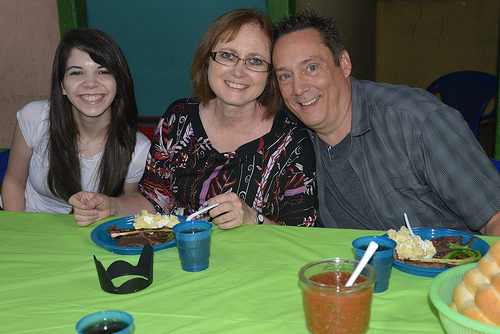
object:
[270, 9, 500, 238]
man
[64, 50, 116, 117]
face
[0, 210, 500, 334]
table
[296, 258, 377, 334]
bowl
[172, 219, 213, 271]
cup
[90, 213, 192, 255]
plate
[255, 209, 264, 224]
wrist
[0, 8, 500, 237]
family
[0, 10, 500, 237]
everyone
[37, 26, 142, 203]
hair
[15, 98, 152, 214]
shirt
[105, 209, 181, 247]
food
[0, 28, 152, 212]
lady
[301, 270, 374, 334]
salsa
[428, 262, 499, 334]
basket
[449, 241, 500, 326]
bread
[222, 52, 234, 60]
eye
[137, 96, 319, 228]
shirt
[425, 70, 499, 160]
chair